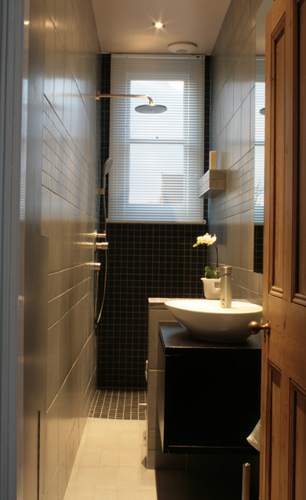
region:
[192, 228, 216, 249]
white bloom on a plant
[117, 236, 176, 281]
black tile on the wall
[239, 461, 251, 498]
wooden plunger handle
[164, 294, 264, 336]
a white porcelain bowl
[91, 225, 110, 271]
chrome fixtures on the wall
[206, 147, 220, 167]
white candle on a shelf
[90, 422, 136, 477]
white tile on the floor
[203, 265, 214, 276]
dark green leaf on a plant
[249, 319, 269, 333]
a brass knob on the door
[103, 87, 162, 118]
a long showerhead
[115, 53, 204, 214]
white bathroom shades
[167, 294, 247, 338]
white sink above counter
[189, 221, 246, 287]
a orchid in a white pot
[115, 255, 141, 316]
black and gray bathroom tile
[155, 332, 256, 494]
black counter and cabinet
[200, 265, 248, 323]
stainless steel push faucet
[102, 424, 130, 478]
white tile bathroom floor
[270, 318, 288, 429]
light brown colored door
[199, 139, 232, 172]
candle on tile shelf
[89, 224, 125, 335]
silver knob for shower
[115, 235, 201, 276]
The back wall is black.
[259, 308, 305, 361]
The door is brown.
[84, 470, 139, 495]
The floor is white.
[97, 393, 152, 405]
Grey part of the floor.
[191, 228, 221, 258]
The flower is white.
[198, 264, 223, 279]
The leaf is green.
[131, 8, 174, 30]
Light on the ceiling.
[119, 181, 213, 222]
The blinds are open.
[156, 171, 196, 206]
Building visible through the blinds.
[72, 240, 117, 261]
Knob on the wall.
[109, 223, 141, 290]
the black tiled wall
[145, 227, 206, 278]
the black tiled wall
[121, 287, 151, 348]
the black tiled wall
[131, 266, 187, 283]
the black tiled wall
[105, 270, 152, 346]
the black tiled wall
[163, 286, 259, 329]
the sink is white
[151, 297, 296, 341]
the sink is white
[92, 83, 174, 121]
a shower head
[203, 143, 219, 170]
a candle on a shelf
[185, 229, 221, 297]
a plant on a table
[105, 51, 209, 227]
a window on a wall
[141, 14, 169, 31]
a light on the ceiling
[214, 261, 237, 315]
the water spiket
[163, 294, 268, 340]
a white sink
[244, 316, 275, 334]
a door knob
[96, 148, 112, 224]
a silver shower head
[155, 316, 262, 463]
a black bathroom vanity